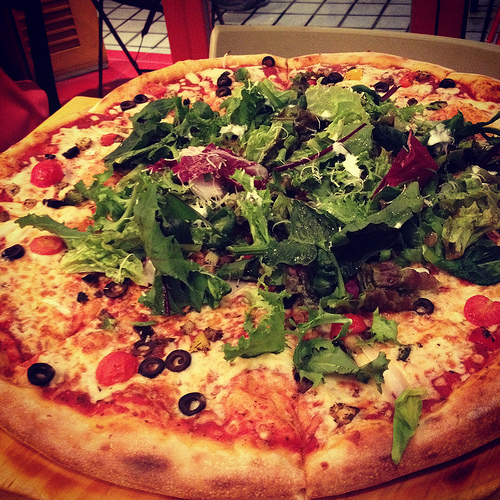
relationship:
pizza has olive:
[0, 50, 499, 499] [261, 56, 275, 68]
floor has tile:
[97, 2, 500, 53] [283, 2, 320, 15]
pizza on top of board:
[0, 50, 499, 499] [1, 97, 498, 497]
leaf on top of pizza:
[306, 85, 364, 119] [0, 50, 499, 499]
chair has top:
[209, 23, 500, 82] [210, 24, 499, 82]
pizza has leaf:
[0, 50, 499, 499] [306, 85, 364, 119]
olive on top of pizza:
[261, 56, 275, 68] [0, 50, 499, 499]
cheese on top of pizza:
[2, 65, 497, 448] [0, 50, 499, 499]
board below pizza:
[1, 97, 498, 497] [0, 50, 499, 499]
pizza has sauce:
[0, 50, 499, 499] [0, 63, 497, 457]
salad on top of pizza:
[145, 144, 270, 193] [0, 50, 499, 499]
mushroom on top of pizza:
[330, 401, 360, 430] [0, 50, 499, 499]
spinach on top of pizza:
[421, 235, 500, 284] [0, 50, 499, 499]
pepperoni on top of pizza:
[30, 235, 63, 256] [0, 50, 499, 499]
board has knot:
[1, 97, 498, 497] [441, 461, 472, 490]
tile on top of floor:
[283, 2, 320, 15] [97, 2, 500, 53]